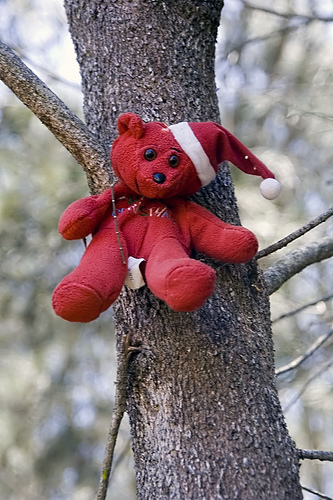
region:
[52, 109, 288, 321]
dark red teddy bear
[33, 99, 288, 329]
stuffed bear hanging on a tree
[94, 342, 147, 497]
skinny stick hanging down from the tree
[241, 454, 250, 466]
small white spot on the tree bark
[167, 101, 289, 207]
Santa hat on the side of the head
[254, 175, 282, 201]
white pom pom on the tip of the hat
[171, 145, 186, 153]
small black line for an eyebrow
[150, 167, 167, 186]
black button for a nose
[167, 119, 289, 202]
red and white hat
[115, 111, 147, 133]
ear on the side of the head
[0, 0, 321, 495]
Red teddy bear against tree trunk.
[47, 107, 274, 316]
Red teddy bear with Santa hat.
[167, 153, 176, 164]
Button eye on teddy bear.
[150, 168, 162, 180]
Button nose on teddy bear.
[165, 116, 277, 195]
Santa hat with white trim and puff.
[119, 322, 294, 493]
Tree trunk with rough bark.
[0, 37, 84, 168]
Rough tree branch extending from trunk.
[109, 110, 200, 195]
Red teddy bear head with button eyes and nose.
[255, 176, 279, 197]
Round puff from Santa hat.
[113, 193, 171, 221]
Multicolored lettering on bear's chest.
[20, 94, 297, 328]
a red stuffed animal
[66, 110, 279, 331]
the animal is a bear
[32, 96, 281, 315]
the bear is attached to the tree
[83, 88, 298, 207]
the bear is wearing a hat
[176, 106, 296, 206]
the hat is red and white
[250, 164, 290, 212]
the tip of the hat has a white ball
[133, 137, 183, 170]
the eyes are brown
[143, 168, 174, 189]
the nose is black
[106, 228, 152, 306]
a tag on the bear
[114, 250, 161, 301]
the tag is white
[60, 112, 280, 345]
the doll is red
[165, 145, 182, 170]
the eye is black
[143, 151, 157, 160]
the eye is black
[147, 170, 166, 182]
the nose is black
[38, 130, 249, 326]
the doll is hanged on the tree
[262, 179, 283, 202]
the end is white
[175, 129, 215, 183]
the hat is white and red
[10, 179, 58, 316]
the background is blurr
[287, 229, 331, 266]
snow is on the branches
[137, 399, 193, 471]
snow is on the trunk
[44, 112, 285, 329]
red christmas teddy bear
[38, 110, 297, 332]
christmas themed child's toy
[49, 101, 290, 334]
christmas themed teddy bear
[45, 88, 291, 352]
teddy bear with a Santa Claus hat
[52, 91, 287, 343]
teddy bear with black eyes and nose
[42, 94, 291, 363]
red fuzzy child's toy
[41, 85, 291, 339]
teddy bear with writing on its chest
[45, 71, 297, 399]
teddy bear nailed to tree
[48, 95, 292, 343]
teddy bear in a tree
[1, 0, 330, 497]
tree with a teddy bear